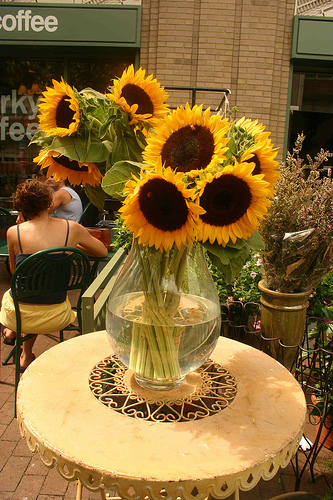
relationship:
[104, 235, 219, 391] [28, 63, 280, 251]
vase holding sunflowers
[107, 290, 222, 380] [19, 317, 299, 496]
water on table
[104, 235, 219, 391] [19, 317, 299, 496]
vase on table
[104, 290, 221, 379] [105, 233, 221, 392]
water in vase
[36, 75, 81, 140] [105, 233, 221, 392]
flower in vase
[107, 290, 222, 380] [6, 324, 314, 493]
water on table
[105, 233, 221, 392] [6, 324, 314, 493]
vase on table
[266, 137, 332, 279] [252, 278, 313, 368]
flower in vase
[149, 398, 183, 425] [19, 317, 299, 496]
heart on table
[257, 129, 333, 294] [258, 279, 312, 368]
flower in vase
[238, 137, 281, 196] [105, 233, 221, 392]
flower in vase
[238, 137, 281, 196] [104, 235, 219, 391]
flower are in vase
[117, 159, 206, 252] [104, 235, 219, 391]
flower in vase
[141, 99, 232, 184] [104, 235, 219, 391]
flower in vase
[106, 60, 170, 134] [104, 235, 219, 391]
flower in a vase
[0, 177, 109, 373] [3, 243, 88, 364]
person on chair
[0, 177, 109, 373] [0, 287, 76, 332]
person wears skirt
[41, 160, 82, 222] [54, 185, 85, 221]
man wears shirt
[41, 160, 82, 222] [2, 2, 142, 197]
man by shop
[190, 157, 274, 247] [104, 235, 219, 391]
flower in vase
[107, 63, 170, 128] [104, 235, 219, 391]
flower in vase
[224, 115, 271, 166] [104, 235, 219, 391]
flower in vase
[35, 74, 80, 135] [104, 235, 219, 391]
flower in vase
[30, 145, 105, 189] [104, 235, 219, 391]
flower in vase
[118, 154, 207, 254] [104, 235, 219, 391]
flower in vase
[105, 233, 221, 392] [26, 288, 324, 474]
vase on table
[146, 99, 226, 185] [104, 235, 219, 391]
flower in vase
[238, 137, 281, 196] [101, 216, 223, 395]
flower in vase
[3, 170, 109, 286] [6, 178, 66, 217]
person has a head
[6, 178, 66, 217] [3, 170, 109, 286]
head of person